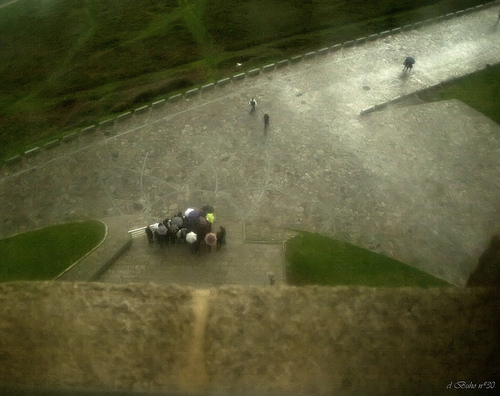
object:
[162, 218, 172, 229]
umbrellas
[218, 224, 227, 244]
people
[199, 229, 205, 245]
person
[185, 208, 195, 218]
umbrella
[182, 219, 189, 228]
person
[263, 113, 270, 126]
person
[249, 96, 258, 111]
person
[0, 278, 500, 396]
edge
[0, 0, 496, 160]
grass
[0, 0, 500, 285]
floor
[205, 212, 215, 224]
umbrella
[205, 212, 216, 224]
part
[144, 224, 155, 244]
people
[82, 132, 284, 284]
wet surface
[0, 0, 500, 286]
road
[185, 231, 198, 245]
umrella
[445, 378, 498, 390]
name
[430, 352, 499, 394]
corner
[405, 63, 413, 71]
people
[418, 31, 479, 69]
light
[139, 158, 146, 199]
lines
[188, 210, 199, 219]
umbrella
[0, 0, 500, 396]
photo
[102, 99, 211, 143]
line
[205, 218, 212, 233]
person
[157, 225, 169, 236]
umbrella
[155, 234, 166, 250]
person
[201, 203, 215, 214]
umbrella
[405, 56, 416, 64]
umbrella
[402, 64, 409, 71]
person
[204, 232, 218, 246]
umbrella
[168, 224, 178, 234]
umbrella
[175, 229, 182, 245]
person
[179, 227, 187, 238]
umbrella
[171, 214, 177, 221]
person